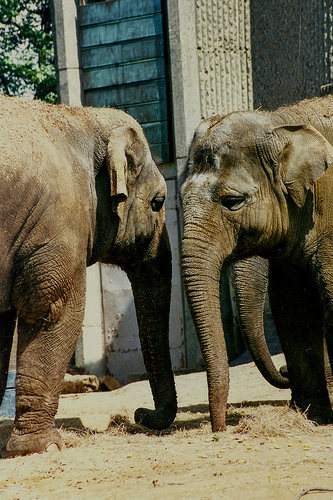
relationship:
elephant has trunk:
[179, 87, 331, 431] [182, 226, 236, 431]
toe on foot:
[38, 423, 73, 463] [0, 424, 76, 455]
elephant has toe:
[1, 97, 187, 450] [38, 423, 73, 463]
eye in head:
[213, 187, 251, 214] [177, 114, 300, 261]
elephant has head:
[1, 97, 187, 450] [177, 114, 300, 261]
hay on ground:
[54, 399, 318, 452] [2, 344, 330, 498]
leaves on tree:
[9, 8, 15, 14] [1, 2, 59, 103]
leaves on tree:
[30, 75, 36, 79] [1, 2, 59, 103]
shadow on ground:
[103, 402, 248, 432] [2, 344, 330, 498]